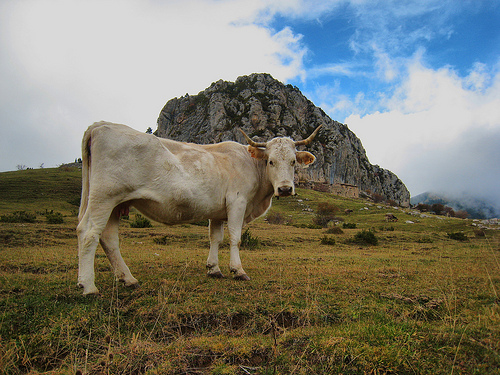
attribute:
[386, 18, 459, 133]
clouds — white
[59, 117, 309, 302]
cow — white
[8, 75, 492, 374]
field — brown, green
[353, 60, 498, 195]
cloud — white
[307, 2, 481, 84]
cloud — white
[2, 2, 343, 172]
cloud — white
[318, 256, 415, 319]
grass — green, brown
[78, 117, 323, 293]
cow — alone, white, walking, light brown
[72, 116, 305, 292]
bull — skinny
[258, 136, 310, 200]
face — white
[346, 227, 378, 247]
shrub — small, dark, green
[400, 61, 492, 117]
clouds — in the picture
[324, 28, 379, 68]
sky — blue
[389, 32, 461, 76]
sky — blue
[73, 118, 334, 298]
bull — white, tan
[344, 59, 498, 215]
cloud — white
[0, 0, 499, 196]
sky — blue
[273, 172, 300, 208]
nose — large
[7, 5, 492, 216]
sky — blue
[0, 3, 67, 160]
clouds — white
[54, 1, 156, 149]
clouds — white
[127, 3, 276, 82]
clouds — white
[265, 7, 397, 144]
clouds — white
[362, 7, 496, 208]
clouds — white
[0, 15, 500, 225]
sky — blue, mostly cloudy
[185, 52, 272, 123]
tower — stone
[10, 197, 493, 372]
field — rocky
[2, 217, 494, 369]
grass — brown, green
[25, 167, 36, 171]
bush — small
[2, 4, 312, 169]
cloud — white, large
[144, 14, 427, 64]
clouds — white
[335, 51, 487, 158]
sky — cloud filled, blue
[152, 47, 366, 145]
hill — rocky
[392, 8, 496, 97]
sky — blue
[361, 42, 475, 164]
cloud — white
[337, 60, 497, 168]
cloud — white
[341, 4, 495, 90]
sky — blue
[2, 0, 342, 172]
clouds — white